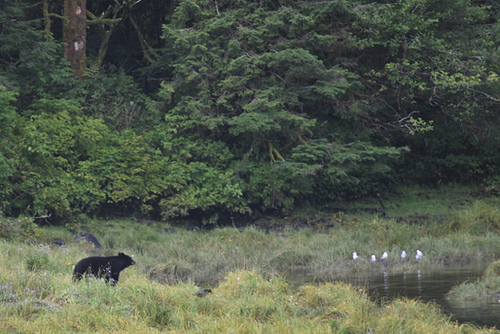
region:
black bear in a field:
[69, 248, 135, 288]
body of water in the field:
[317, 255, 498, 331]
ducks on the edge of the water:
[349, 248, 424, 263]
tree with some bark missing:
[62, 1, 92, 78]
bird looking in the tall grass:
[192, 284, 217, 301]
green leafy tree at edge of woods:
[1, 100, 243, 216]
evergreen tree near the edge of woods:
[174, 0, 403, 210]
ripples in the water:
[371, 277, 444, 299]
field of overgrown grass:
[2, 218, 313, 332]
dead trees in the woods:
[87, 2, 158, 65]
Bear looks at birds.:
[65, 241, 144, 292]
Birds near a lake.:
[339, 244, 429, 271]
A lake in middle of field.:
[217, 250, 497, 325]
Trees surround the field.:
[2, 32, 495, 231]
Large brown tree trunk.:
[62, 4, 89, 85]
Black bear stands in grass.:
[67, 237, 139, 289]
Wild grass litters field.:
[7, 280, 432, 327]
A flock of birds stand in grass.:
[338, 237, 437, 269]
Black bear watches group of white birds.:
[65, 220, 430, 294]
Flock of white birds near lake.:
[305, 233, 499, 319]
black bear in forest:
[65, 238, 145, 284]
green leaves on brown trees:
[9, 15, 45, 53]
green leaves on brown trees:
[23, 73, 82, 118]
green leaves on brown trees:
[42, 133, 97, 178]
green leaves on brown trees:
[123, 141, 208, 194]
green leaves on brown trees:
[223, 40, 271, 91]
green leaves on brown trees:
[218, 112, 306, 179]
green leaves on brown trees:
[326, 33, 394, 97]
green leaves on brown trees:
[341, 77, 404, 139]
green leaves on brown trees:
[414, 38, 465, 100]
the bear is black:
[61, 243, 146, 309]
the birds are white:
[340, 240, 427, 270]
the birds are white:
[328, 225, 440, 282]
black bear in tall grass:
[58, 229, 140, 299]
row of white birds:
[337, 244, 443, 267]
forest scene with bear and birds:
[2, 71, 469, 321]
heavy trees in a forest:
[14, 1, 456, 242]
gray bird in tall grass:
[189, 279, 216, 306]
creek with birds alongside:
[250, 219, 496, 296]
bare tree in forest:
[51, 0, 136, 89]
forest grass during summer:
[158, 234, 323, 326]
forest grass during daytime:
[352, 159, 482, 248]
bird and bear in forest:
[40, 168, 231, 313]